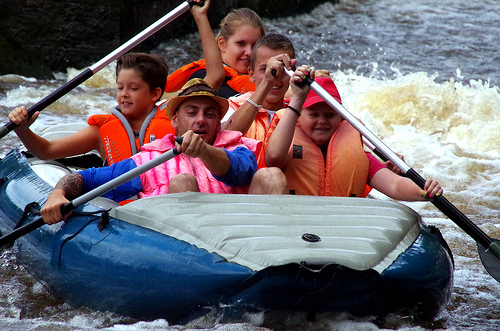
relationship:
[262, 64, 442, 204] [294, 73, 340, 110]
boy wearing red hat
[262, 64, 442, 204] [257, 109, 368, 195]
boy wearing vest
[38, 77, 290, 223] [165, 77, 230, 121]
man wearing hat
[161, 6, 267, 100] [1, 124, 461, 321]
girl back raft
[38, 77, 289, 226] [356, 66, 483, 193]
man in rapids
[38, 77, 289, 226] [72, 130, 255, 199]
man wears jacket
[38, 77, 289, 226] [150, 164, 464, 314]
man in raft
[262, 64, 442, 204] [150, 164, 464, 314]
boy in raft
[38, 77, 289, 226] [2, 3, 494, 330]
man doing sports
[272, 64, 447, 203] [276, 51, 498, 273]
boy holding paddle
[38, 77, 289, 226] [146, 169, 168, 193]
man wears vest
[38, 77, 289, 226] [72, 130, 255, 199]
man wearing jacket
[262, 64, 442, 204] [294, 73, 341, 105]
boy wearing red hat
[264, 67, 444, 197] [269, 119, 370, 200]
girl wearing vest